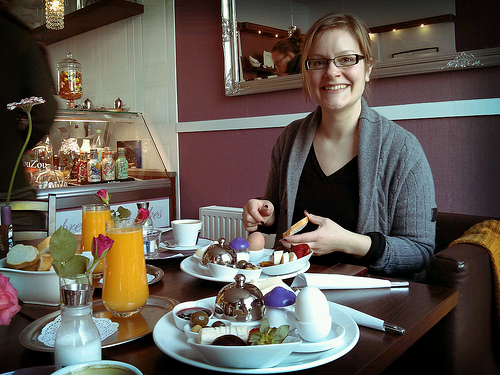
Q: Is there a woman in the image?
A: Yes, there is a woman.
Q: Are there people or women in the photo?
A: Yes, there is a woman.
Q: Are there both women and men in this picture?
A: No, there is a woman but no men.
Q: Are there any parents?
A: No, there are no parents.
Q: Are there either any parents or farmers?
A: No, there are no parents or farmers.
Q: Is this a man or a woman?
A: This is a woman.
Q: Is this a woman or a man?
A: This is a woman.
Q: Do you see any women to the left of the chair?
A: Yes, there is a woman to the left of the chair.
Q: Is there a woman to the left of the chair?
A: Yes, there is a woman to the left of the chair.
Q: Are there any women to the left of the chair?
A: Yes, there is a woman to the left of the chair.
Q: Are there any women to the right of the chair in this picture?
A: No, the woman is to the left of the chair.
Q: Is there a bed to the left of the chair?
A: No, there is a woman to the left of the chair.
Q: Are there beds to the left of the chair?
A: No, there is a woman to the left of the chair.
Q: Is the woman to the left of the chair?
A: Yes, the woman is to the left of the chair.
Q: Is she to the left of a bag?
A: No, the woman is to the left of the chair.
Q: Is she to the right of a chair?
A: No, the woman is to the left of a chair.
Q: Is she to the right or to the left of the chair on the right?
A: The woman is to the left of the chair.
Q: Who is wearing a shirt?
A: The woman is wearing a shirt.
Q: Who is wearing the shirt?
A: The woman is wearing a shirt.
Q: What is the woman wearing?
A: The woman is wearing a shirt.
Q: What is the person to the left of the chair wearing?
A: The woman is wearing a shirt.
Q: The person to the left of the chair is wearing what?
A: The woman is wearing a shirt.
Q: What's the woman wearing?
A: The woman is wearing a shirt.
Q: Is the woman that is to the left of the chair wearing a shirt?
A: Yes, the woman is wearing a shirt.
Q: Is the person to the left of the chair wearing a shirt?
A: Yes, the woman is wearing a shirt.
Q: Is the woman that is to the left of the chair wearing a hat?
A: No, the woman is wearing a shirt.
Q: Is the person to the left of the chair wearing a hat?
A: No, the woman is wearing a shirt.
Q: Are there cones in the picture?
A: No, there are no cones.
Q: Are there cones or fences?
A: No, there are no cones or fences.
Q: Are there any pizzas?
A: No, there are no pizzas.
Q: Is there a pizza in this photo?
A: No, there are no pizzas.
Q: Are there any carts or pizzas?
A: No, there are no pizzas or carts.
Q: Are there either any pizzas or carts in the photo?
A: No, there are no pizzas or carts.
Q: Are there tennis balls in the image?
A: No, there are no tennis balls.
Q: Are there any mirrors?
A: Yes, there is a mirror.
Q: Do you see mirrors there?
A: Yes, there is a mirror.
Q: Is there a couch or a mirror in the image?
A: Yes, there is a mirror.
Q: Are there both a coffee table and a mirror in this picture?
A: No, there is a mirror but no coffee tables.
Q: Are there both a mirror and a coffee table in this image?
A: No, there is a mirror but no coffee tables.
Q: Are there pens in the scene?
A: No, there are no pens.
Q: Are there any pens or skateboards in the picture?
A: No, there are no pens or skateboards.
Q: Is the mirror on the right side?
A: Yes, the mirror is on the right of the image.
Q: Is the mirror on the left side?
A: No, the mirror is on the right of the image.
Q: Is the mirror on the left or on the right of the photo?
A: The mirror is on the right of the image.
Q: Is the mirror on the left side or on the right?
A: The mirror is on the right of the image.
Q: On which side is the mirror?
A: The mirror is on the right of the image.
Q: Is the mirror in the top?
A: Yes, the mirror is in the top of the image.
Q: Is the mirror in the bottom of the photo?
A: No, the mirror is in the top of the image.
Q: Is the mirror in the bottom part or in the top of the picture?
A: The mirror is in the top of the image.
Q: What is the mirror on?
A: The mirror is on the wall.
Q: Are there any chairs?
A: Yes, there is a chair.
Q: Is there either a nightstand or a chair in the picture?
A: Yes, there is a chair.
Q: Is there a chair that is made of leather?
A: Yes, there is a chair that is made of leather.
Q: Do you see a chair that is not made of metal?
A: Yes, there is a chair that is made of leather.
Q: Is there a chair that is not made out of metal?
A: Yes, there is a chair that is made of leather.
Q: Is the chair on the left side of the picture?
A: No, the chair is on the right of the image.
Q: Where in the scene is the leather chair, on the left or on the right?
A: The chair is on the right of the image.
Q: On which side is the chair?
A: The chair is on the right of the image.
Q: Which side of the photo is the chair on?
A: The chair is on the right of the image.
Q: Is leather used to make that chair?
A: Yes, the chair is made of leather.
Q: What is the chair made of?
A: The chair is made of leather.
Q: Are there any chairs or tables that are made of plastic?
A: No, there is a chair but it is made of leather.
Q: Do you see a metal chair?
A: No, there is a chair but it is made of leather.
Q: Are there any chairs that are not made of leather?
A: No, there is a chair but it is made of leather.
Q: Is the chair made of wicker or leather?
A: The chair is made of leather.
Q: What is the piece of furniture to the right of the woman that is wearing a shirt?
A: The piece of furniture is a chair.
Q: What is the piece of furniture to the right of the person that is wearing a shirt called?
A: The piece of furniture is a chair.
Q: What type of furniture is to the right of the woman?
A: The piece of furniture is a chair.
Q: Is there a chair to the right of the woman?
A: Yes, there is a chair to the right of the woman.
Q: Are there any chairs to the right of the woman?
A: Yes, there is a chair to the right of the woman.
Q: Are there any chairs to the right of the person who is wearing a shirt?
A: Yes, there is a chair to the right of the woman.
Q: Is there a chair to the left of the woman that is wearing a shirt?
A: No, the chair is to the right of the woman.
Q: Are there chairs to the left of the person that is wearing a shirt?
A: No, the chair is to the right of the woman.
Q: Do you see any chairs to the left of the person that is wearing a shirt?
A: No, the chair is to the right of the woman.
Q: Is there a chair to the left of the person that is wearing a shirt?
A: No, the chair is to the right of the woman.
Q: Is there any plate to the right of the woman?
A: No, there is a chair to the right of the woman.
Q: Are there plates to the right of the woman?
A: No, there is a chair to the right of the woman.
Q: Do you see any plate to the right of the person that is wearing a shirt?
A: No, there is a chair to the right of the woman.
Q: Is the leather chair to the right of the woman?
A: Yes, the chair is to the right of the woman.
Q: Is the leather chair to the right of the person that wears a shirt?
A: Yes, the chair is to the right of the woman.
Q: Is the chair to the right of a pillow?
A: No, the chair is to the right of the woman.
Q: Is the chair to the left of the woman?
A: No, the chair is to the right of the woman.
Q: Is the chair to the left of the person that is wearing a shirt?
A: No, the chair is to the right of the woman.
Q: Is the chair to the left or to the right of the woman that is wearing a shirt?
A: The chair is to the right of the woman.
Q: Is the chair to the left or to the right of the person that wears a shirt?
A: The chair is to the right of the woman.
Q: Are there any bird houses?
A: No, there are no bird houses.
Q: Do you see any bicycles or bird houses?
A: No, there are no bird houses or bicycles.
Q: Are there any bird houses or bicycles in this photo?
A: No, there are no bird houses or bicycles.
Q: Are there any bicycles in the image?
A: No, there are no bicycles.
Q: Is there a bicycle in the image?
A: No, there are no bicycles.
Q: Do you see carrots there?
A: No, there are no carrots.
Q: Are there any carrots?
A: No, there are no carrots.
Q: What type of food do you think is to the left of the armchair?
A: The food is an egg.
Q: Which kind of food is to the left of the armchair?
A: The food is an egg.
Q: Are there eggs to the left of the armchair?
A: Yes, there is an egg to the left of the armchair.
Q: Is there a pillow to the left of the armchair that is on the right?
A: No, there is an egg to the left of the armchair.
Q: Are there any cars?
A: No, there are no cars.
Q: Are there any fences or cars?
A: No, there are no cars or fences.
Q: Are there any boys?
A: No, there are no boys.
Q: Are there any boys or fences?
A: No, there are no boys or fences.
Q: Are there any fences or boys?
A: No, there are no boys or fences.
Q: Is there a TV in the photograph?
A: No, there are no televisions.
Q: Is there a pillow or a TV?
A: No, there are no televisions or pillows.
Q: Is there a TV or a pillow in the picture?
A: No, there are no televisions or pillows.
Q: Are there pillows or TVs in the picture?
A: No, there are no TVs or pillows.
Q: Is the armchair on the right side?
A: Yes, the armchair is on the right of the image.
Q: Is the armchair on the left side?
A: No, the armchair is on the right of the image.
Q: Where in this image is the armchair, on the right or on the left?
A: The armchair is on the right of the image.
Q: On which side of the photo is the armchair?
A: The armchair is on the right of the image.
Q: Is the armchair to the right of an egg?
A: Yes, the armchair is to the right of an egg.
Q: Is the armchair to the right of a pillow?
A: No, the armchair is to the right of an egg.